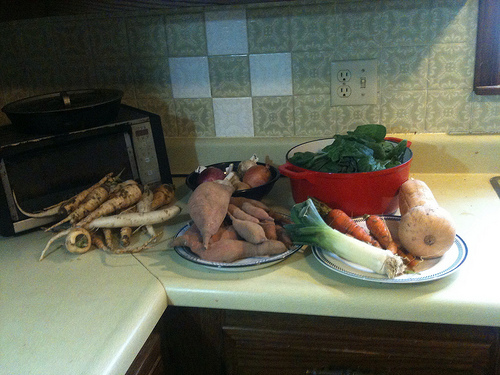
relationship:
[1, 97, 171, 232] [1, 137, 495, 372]
microwave on counter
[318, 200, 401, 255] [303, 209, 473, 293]
carrots on plate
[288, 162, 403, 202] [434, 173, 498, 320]
pot on counter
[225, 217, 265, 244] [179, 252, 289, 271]
sweet potato on plate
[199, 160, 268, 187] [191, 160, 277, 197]
onions in bowl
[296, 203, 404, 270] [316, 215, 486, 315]
leek in plate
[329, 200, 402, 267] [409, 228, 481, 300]
carrots on plate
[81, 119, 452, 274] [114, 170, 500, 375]
vegetables on table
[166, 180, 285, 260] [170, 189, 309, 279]
potatoes on plate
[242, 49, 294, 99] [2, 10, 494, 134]
tile on wall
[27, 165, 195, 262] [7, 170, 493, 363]
parsnips on table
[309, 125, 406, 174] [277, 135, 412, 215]
greens in a pot